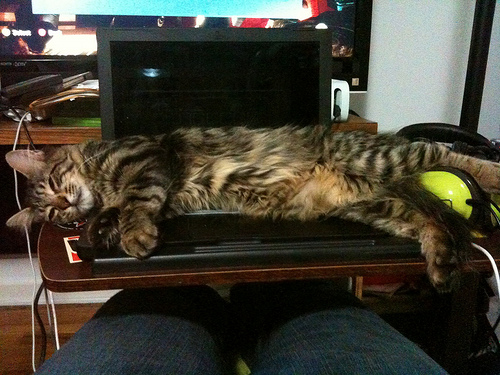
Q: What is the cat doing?
A: Sleeping.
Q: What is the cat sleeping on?
A: A computer.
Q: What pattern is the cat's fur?
A: Stripes.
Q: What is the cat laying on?
A: A keyboard.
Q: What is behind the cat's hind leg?
A: Wires.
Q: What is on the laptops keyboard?
A: Comfortable cat.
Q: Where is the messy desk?
A: Behind the laptop.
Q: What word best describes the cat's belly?
A: Velutinous.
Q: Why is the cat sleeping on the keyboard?
A: Favorite place.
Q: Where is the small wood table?
A: Under the laptop.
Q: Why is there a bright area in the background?
A: Television.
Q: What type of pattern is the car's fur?
A: Tiger striped.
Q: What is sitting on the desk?
A: Computer.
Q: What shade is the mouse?
A: Yellow and black.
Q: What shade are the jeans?
A: Blue.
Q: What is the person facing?
A: Television.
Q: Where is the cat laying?
A: Laptop.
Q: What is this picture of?
A: Sleeping cat.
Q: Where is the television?
A: Behind laptop.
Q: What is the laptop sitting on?
A: Tray.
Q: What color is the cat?
A: Black and grey.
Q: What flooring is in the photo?
A: Wood.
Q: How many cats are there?
A: 1.